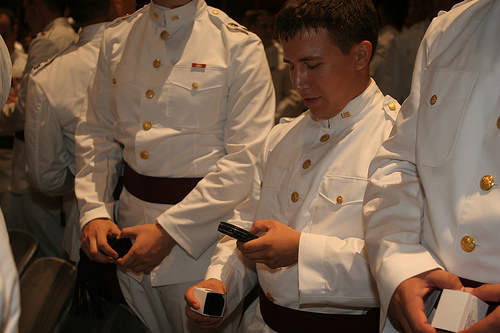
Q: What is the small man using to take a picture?
A: A phone.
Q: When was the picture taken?
A: During a ceremony.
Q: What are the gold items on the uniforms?
A: Buttons.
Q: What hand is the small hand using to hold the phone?
A: Left.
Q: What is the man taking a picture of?
A: A box.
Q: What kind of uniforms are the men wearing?
A: Military.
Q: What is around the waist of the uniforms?
A: Belts.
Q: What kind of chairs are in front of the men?
A: Folding chairs.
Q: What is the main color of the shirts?
A: White.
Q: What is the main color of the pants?
A: White.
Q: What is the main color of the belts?
A: Brown.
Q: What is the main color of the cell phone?
A: Black.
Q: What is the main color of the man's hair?
A: Brown.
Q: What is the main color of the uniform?
A: White.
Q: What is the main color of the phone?
A: Black.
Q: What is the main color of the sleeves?
A: White.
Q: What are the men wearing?
A: White uniforms.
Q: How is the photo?
A: Clear.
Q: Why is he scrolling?
A: Texting.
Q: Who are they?
A: Cooks.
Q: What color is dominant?
A: White.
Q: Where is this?
A: At a naval event.